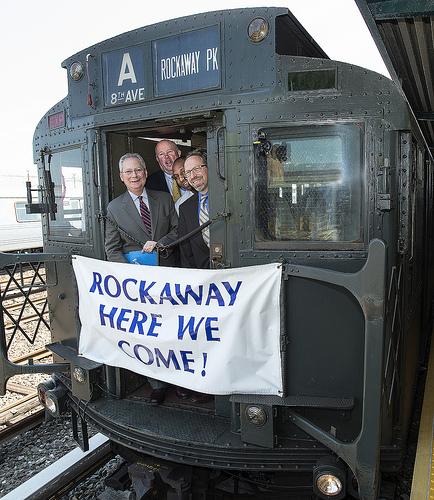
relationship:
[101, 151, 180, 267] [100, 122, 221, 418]
person standing in doorway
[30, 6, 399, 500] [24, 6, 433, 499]
back of train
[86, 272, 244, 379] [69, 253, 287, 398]
words are on banner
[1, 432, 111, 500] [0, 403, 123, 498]
track in gravel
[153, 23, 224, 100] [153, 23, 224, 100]
sign are on sign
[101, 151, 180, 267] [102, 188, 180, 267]
person in suit and tie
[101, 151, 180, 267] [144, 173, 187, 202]
person in suit and tie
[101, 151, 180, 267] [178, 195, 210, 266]
person in suit and tie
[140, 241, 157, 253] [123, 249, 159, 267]
hand over folder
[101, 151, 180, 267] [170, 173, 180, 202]
person in yellow tie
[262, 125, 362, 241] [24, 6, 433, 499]
window of train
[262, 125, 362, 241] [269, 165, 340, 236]
window with reflection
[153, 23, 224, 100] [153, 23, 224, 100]
sign proclaims sign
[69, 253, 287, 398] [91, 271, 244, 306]
banner proclaims destination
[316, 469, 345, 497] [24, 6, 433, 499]
headlight on train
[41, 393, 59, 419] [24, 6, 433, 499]
headlight on train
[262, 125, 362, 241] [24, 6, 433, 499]
window in train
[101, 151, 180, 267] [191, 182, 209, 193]
person with beard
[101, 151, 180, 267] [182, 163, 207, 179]
person wearing glasses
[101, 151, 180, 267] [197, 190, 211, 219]
person in light blue shirt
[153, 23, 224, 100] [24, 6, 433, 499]
sign on train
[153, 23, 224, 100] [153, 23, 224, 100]
sign has sign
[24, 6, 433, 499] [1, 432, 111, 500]
train on track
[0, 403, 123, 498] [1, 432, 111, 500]
gravel surrounds track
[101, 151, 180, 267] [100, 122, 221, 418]
person are standing in doorway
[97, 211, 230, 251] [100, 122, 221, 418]
safety strap across doorway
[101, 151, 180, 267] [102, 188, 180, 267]
person wearing suit and tie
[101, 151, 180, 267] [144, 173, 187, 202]
person wearing suit and tie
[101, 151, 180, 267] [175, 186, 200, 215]
person wearing suit and tie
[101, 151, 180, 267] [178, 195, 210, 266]
person wearing suit and tie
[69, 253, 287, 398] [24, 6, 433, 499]
banner on train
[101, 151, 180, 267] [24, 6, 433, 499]
person are riding on train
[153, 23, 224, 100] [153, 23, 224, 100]
sign says sign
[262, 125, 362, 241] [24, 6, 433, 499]
window to train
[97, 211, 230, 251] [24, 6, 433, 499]
safety strap on train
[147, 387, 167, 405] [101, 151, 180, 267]
shoe on person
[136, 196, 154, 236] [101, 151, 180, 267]
tie on person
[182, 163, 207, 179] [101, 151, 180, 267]
glasses are worn by person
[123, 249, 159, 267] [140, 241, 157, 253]
folder in hand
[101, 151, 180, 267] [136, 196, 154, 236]
person with tie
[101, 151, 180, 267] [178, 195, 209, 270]
person in black jacket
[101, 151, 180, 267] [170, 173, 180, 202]
person with yellow tie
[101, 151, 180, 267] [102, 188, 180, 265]
person in light grey jacket